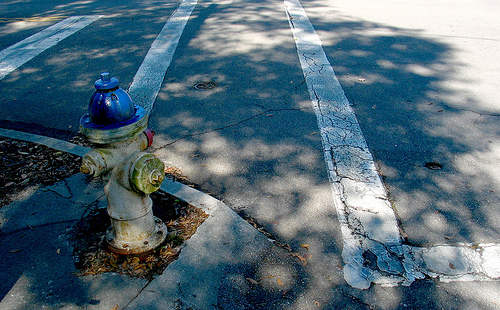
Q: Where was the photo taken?
A: It was taken at the street.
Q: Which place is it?
A: It is a street.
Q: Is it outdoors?
A: Yes, it is outdoors.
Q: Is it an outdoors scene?
A: Yes, it is outdoors.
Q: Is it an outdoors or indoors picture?
A: It is outdoors.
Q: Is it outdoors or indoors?
A: It is outdoors.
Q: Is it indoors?
A: No, it is outdoors.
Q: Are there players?
A: No, there are no players.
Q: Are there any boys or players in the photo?
A: No, there are no players or boys.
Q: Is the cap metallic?
A: Yes, the cap is metallic.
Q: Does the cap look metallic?
A: Yes, the cap is metallic.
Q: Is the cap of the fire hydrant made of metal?
A: Yes, the cap is made of metal.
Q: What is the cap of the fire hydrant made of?
A: The cap is made of metal.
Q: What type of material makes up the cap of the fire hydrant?
A: The cap is made of metal.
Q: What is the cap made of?
A: The cap is made of metal.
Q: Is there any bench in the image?
A: No, there are no benches.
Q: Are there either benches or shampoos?
A: No, there are no benches or shampoos.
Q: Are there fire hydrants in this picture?
A: Yes, there is a fire hydrant.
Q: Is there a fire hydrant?
A: Yes, there is a fire hydrant.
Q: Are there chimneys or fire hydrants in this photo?
A: Yes, there is a fire hydrant.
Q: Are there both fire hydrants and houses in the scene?
A: No, there is a fire hydrant but no houses.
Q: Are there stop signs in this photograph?
A: No, there are no stop signs.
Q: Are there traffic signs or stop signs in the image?
A: No, there are no stop signs or traffic signs.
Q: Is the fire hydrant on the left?
A: Yes, the fire hydrant is on the left of the image.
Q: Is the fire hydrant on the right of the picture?
A: No, the fire hydrant is on the left of the image.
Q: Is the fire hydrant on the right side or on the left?
A: The fire hydrant is on the left of the image.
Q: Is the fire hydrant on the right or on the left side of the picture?
A: The fire hydrant is on the left of the image.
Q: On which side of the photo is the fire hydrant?
A: The fire hydrant is on the left of the image.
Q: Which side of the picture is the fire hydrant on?
A: The fire hydrant is on the left of the image.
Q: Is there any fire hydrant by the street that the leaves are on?
A: Yes, there is a fire hydrant by the street.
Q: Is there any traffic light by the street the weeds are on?
A: No, there is a fire hydrant by the street.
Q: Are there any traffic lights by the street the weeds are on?
A: No, there is a fire hydrant by the street.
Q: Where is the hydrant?
A: The hydrant is on the sidewalk.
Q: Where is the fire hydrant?
A: The hydrant is on the sidewalk.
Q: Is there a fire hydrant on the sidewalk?
A: Yes, there is a fire hydrant on the sidewalk.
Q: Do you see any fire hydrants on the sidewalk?
A: Yes, there is a fire hydrant on the sidewalk.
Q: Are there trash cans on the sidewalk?
A: No, there is a fire hydrant on the sidewalk.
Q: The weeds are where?
A: The weeds are on the street.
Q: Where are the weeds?
A: The weeds are on the street.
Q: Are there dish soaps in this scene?
A: No, there are no dish soaps.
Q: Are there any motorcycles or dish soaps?
A: No, there are no dish soaps or motorcycles.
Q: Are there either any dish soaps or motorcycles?
A: No, there are no dish soaps or motorcycles.